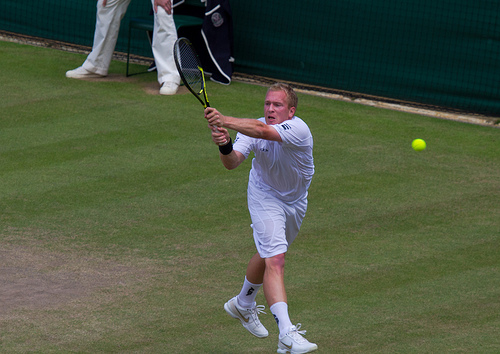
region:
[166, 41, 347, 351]
a man playing osme tennis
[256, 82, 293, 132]
the head of a man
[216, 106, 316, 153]
the left arm of a man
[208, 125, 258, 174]
the right arm of a man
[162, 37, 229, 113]
a black and yellow tennis racket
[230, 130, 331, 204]
the torso of a man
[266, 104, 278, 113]
the nose of a man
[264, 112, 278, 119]
the mouth of a man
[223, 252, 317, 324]
the legs of a man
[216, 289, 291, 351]
the shoes of a man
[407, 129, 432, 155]
The ball is in the air.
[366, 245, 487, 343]
The tennis court is green.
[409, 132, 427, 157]
The ball is green.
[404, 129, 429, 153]
The ball is round.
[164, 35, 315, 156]
The man is swinging a tennis racket.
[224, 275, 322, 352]
The man is wearing white tennis shoes.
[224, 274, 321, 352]
The man is wearing white socks.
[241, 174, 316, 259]
The man is wearing white shorts.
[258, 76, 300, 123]
The man has blonde hair.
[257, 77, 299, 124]
The man has short hair.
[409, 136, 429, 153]
tennis ball in midair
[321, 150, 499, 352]
green grass on a tennis court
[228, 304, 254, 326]
Nike logo on the man's white shoe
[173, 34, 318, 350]
man wearing white and holding a tennis racket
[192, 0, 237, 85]
jacket draped over the back of a chair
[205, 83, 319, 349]
tennis player wearing white clothes and a black wristband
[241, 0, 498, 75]
green fence behind the tennis court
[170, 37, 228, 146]
tennis racket in the man's hands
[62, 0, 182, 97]
person in the background wearing white pants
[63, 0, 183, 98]
legs in the background and white shoes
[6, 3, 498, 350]
Man swinging tennis racket.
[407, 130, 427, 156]
Green tennis ball in mid air.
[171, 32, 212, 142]
Tennis racket with green designs on it.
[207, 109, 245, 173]
Black arm band on right arm.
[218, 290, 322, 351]
White tennis shoes with white shoe strings.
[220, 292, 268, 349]
Nike sign on white tennis shoes.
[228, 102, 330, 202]
White short sleeved shirt with blue design on sleeve.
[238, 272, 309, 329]
Blue design on white socks.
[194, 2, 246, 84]
Tennis bag with white stripe.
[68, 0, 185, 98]
Man wearing long pants with cuff.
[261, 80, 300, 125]
The man's hair is blonde.